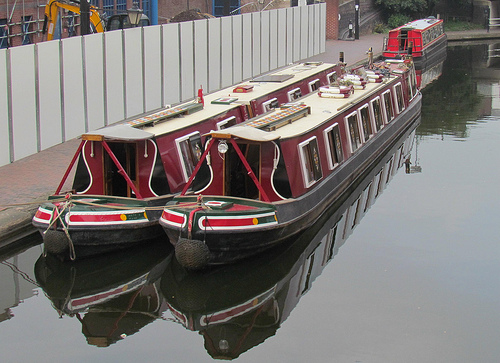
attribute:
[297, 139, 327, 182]
window — boat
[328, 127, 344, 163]
window — boat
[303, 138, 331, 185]
window — boat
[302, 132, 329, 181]
window — boat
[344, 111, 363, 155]
window — boat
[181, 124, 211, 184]
window — boat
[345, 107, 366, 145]
window — boat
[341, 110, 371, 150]
window — boat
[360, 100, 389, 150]
window — boat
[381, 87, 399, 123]
window — boat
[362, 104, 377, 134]
window — boat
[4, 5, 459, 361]
scene — outdoors 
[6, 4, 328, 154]
fence — white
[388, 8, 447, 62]
boat — bright red , water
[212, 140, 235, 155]
boat — light 